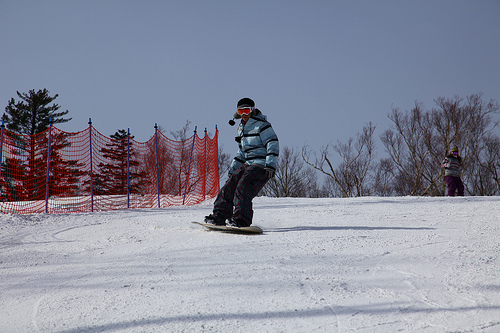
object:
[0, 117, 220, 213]
fence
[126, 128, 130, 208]
post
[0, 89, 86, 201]
tree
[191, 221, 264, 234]
snowboard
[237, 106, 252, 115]
goggles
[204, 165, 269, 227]
pants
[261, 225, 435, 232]
shadow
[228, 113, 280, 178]
jacket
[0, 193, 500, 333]
hill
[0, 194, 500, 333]
snow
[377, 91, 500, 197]
tree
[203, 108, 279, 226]
clothing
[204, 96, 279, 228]
girl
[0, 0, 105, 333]
left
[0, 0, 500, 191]
sky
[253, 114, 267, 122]
hood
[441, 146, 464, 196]
person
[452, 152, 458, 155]
goggles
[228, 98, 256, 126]
hat